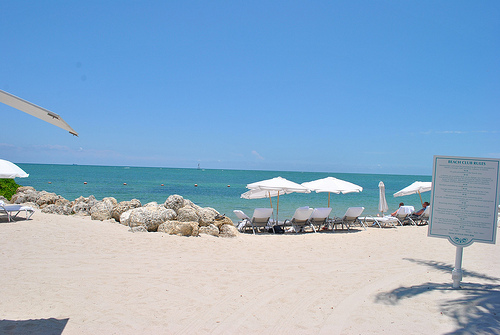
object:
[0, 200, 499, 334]
sand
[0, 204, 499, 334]
beach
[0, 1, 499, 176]
sky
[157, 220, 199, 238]
rocks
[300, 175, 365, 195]
umbrellas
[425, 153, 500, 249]
sign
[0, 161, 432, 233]
water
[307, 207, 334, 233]
chairs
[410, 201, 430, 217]
people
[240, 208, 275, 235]
recliner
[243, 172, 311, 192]
umbrella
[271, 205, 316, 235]
chair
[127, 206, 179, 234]
boulders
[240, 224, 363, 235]
shade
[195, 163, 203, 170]
ship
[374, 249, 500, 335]
shadow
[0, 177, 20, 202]
tree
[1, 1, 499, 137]
blue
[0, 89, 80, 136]
panel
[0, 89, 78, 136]
truck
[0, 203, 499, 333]
ground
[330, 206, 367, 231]
seats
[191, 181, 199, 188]
floats